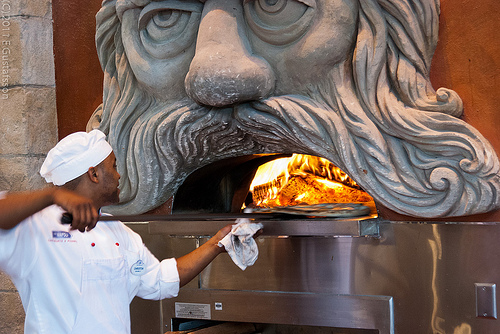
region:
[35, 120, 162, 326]
Cook putting pizza in oven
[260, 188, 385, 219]
Pizza inside large oven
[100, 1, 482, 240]
Large stone faced oven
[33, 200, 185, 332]
White cook's uniform on man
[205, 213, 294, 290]
White towel on man's hand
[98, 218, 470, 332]
Stainless steele oven bottom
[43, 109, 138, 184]
White chef hat on man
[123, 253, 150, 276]
White and green nametag on man's outfit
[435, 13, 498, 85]
orange wall behind stove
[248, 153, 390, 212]
Flames burning inside oven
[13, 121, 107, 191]
The man has on chef hat.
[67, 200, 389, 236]
Long stick in the oven.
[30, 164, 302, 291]
Man putting pizza in oven.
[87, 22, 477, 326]
A commercial oven with face on top.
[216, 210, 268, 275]
The man is holding a white rag.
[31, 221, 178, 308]
The man is wearing chef uniform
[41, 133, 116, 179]
The hat is white.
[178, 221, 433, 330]
The oven is stainless steel.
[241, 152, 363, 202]
Fire in the oven.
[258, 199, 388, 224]
Pizza on the wood board.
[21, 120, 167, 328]
man wearing chefs uniform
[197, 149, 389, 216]
fire inside of pizza oven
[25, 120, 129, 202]
man wearing a chefs hat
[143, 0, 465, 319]
stainless steel pizza oven with a sculpture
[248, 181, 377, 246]
pizza going into oven to be cooked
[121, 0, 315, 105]
nose and eyes of sculpture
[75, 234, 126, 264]
two red buttons on chefs uniform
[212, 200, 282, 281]
white rag used by chef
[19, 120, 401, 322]
chef cooking a pizza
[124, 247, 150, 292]
name tag worn by chef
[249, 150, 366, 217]
pit of fire and hot coals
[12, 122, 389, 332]
man taking a pan out of the fire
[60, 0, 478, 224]
face shaped oven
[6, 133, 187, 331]
man wearing a chefs hat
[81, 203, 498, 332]
silver bottom of an oven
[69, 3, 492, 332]
huge brick oven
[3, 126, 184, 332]
chef with a white shirt on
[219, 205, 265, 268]
napkin in a mans hand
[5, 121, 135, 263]
man with dark skin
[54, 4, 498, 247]
oven against a brick red wall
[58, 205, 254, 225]
a long stick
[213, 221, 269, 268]
a white rag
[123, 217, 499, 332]
a large gray oven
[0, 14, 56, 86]
a large gray stone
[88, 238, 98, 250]
a small red button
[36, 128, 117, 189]
a man's white hat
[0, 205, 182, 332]
a white uniform shirt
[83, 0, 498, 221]
a large gray sculpture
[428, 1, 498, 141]
part of a brown painted wall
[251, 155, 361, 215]
a hot oven fire